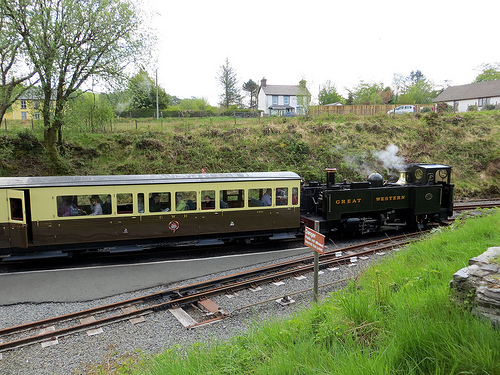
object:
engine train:
[298, 163, 454, 242]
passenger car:
[0, 169, 300, 266]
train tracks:
[0, 240, 430, 375]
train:
[1, 162, 458, 263]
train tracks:
[452, 196, 499, 218]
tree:
[0, 0, 156, 161]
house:
[256, 76, 311, 117]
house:
[432, 79, 500, 113]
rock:
[450, 244, 499, 331]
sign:
[304, 226, 325, 257]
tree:
[68, 89, 114, 137]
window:
[57, 194, 112, 217]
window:
[116, 193, 134, 214]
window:
[137, 193, 145, 213]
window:
[149, 192, 172, 213]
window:
[175, 191, 197, 211]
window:
[201, 190, 216, 211]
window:
[220, 189, 245, 209]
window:
[248, 188, 271, 207]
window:
[276, 187, 288, 205]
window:
[292, 187, 298, 205]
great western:
[336, 195, 406, 204]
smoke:
[334, 139, 407, 179]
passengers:
[89, 197, 103, 216]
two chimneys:
[260, 78, 307, 87]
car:
[386, 105, 417, 115]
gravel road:
[2, 231, 440, 375]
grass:
[117, 209, 500, 374]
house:
[1, 86, 70, 121]